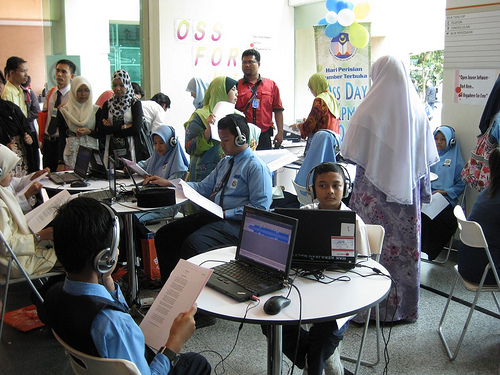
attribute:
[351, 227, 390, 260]
chair — white, folding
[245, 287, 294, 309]
mouse — black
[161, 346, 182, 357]
watch — black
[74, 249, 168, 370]
shirt — blue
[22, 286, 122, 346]
vest — dark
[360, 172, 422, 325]
dress — floral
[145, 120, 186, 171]
headscarf — blue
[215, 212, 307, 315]
laptop — black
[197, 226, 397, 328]
table — small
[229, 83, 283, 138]
shirt — red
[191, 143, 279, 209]
shirt — blue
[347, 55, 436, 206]
headscarf — white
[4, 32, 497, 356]
people — sitting